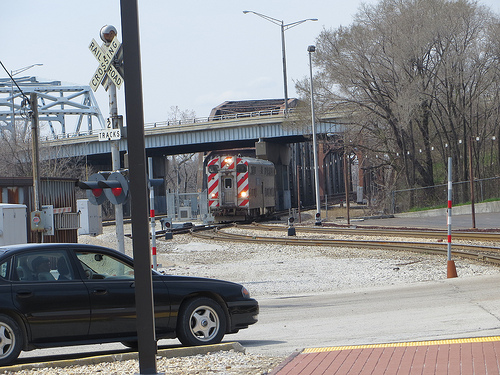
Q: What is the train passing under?
A: A bridge.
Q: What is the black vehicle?
A: A car.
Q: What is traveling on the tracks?
A: A train.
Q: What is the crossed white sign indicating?
A: Railroad crossing.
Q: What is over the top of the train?
A: A bridge.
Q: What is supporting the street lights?
A: A light pole.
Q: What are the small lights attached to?
A: A string support.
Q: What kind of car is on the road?
A: A black sedan.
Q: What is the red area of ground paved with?
A: Red bricks.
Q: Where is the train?
A: On the tracks.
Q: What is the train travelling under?
A: Bridge.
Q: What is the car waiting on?
A: Train crossing.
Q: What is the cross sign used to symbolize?
A: Train crossing.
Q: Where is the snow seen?
A: On the ground.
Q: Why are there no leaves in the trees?
A: Winter.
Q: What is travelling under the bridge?
A: Train.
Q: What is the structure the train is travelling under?
A: Bridge.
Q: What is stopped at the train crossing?
A: Car.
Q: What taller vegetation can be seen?
A: Trees.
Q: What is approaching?
A: A train.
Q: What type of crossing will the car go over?
A: Railroad crossing.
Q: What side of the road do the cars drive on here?
A: Right.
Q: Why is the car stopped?
A: Train is coming.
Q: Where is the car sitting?
A: On the road.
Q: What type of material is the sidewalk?
A: Brick.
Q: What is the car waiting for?
A: The train.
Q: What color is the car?
A: Black.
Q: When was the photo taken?
A: Daytime.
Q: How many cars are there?
A: One.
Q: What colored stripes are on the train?
A: Red and White.